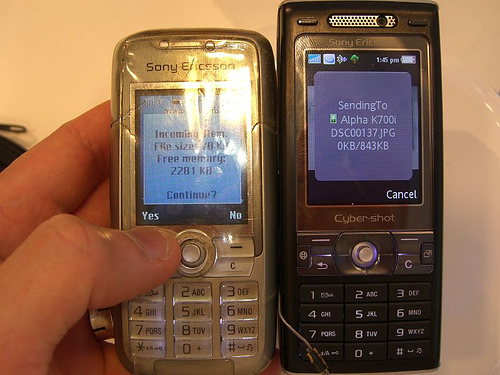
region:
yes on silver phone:
[136, 208, 166, 226]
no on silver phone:
[218, 202, 248, 224]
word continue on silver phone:
[162, 185, 210, 203]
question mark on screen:
[208, 187, 218, 198]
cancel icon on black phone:
[372, 178, 418, 206]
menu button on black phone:
[358, 246, 373, 261]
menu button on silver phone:
[180, 237, 203, 267]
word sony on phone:
[140, 55, 180, 77]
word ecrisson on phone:
[176, 57, 237, 74]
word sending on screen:
[333, 98, 377, 115]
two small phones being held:
[0, 0, 443, 371]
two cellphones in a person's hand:
[0, 0, 445, 372]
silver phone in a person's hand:
[1, 1, 278, 372]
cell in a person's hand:
[4, 1, 281, 373]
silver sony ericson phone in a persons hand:
[1, 1, 278, 374]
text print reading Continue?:
[162, 186, 222, 201]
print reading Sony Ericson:
[141, 57, 236, 74]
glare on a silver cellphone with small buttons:
[105, 25, 277, 373]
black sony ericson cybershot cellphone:
[274, 1, 444, 374]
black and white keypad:
[296, 283, 439, 368]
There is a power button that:
[363, 245, 384, 307]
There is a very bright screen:
[333, 103, 367, 176]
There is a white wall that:
[477, 143, 497, 243]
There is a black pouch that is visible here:
[2, 120, 12, 154]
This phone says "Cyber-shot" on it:
[338, 210, 399, 270]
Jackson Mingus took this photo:
[99, 108, 251, 298]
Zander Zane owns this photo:
[98, 109, 254, 371]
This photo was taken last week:
[121, 115, 263, 360]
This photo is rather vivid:
[86, 125, 284, 360]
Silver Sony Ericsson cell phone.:
[111, 28, 276, 373]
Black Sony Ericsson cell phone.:
[277, 0, 444, 373]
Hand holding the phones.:
[1, 97, 178, 374]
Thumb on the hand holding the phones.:
[0, 213, 180, 374]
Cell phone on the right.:
[276, 3, 443, 374]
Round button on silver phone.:
[177, 238, 206, 267]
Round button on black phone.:
[353, 241, 378, 266]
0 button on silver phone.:
[173, 338, 211, 358]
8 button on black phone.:
[344, 322, 387, 339]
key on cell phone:
[222, 298, 255, 315]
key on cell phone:
[299, 304, 333, 318]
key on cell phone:
[343, 302, 377, 323]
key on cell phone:
[300, 284, 340, 306]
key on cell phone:
[352, 323, 380, 342]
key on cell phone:
[351, 240, 383, 269]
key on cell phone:
[397, 258, 424, 275]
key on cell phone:
[311, 255, 336, 273]